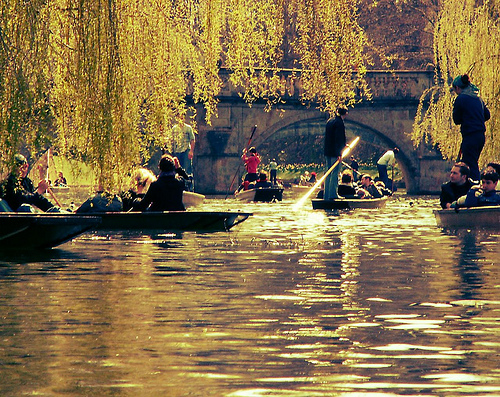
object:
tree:
[402, 0, 500, 173]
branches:
[257, 29, 269, 99]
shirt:
[241, 154, 260, 174]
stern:
[252, 186, 282, 201]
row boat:
[233, 186, 281, 202]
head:
[448, 163, 471, 183]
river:
[0, 175, 499, 395]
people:
[437, 162, 476, 209]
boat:
[432, 206, 500, 229]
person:
[463, 168, 500, 206]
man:
[321, 109, 346, 202]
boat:
[310, 197, 397, 210]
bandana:
[453, 76, 481, 96]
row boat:
[310, 194, 392, 209]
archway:
[239, 118, 418, 199]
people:
[3, 154, 65, 211]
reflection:
[320, 210, 348, 333]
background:
[0, 0, 499, 396]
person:
[268, 159, 278, 185]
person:
[252, 173, 274, 188]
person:
[306, 170, 316, 185]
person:
[356, 175, 381, 199]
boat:
[233, 188, 284, 201]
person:
[129, 157, 195, 211]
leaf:
[85, 202, 94, 207]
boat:
[70, 211, 252, 231]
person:
[450, 75, 488, 174]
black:
[458, 94, 478, 121]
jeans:
[323, 156, 339, 200]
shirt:
[322, 115, 347, 159]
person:
[241, 148, 260, 190]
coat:
[240, 154, 262, 174]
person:
[373, 147, 400, 179]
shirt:
[375, 148, 397, 168]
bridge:
[182, 64, 438, 199]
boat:
[0, 216, 103, 258]